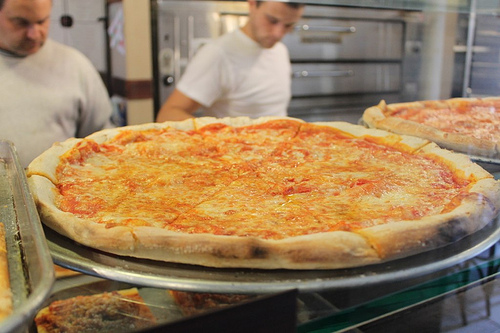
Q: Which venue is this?
A: This is a kitchen.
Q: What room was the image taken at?
A: It was taken at the kitchen.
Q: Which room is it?
A: It is a kitchen.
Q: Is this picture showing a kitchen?
A: Yes, it is showing a kitchen.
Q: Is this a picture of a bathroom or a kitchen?
A: It is showing a kitchen.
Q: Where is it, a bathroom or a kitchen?
A: It is a kitchen.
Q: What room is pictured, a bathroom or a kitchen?
A: It is a kitchen.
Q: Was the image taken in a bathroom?
A: No, the picture was taken in a kitchen.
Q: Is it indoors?
A: Yes, it is indoors.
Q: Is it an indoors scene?
A: Yes, it is indoors.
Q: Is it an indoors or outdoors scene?
A: It is indoors.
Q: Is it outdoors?
A: No, it is indoors.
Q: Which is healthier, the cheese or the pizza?
A: The cheese is healthier than the pizza.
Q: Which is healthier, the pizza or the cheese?
A: The cheese is healthier than the pizza.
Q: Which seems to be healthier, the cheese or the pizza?
A: The cheese is healthier than the pizza.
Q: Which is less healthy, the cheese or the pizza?
A: The pizza is less healthy than the cheese.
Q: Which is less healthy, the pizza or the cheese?
A: The pizza is less healthy than the cheese.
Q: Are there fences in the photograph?
A: No, there are no fences.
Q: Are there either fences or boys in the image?
A: No, there are no fences or boys.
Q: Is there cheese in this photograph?
A: Yes, there is cheese.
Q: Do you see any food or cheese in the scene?
A: Yes, there is cheese.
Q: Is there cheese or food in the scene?
A: Yes, there is cheese.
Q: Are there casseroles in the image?
A: No, there are no casseroles.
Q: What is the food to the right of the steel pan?
A: The food is cheese.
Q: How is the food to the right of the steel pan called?
A: The food is cheese.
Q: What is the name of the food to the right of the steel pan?
A: The food is cheese.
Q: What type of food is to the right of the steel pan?
A: The food is cheese.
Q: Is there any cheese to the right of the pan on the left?
A: Yes, there is cheese to the right of the pan.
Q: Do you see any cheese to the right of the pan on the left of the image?
A: Yes, there is cheese to the right of the pan.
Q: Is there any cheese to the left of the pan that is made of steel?
A: No, the cheese is to the right of the pan.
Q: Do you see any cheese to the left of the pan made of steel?
A: No, the cheese is to the right of the pan.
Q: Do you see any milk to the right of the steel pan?
A: No, there is cheese to the right of the pan.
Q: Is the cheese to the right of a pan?
A: Yes, the cheese is to the right of a pan.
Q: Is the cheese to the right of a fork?
A: No, the cheese is to the right of a pan.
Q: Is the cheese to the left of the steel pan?
A: No, the cheese is to the right of the pan.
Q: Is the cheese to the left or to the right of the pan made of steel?
A: The cheese is to the right of the pan.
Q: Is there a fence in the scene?
A: No, there are no fences.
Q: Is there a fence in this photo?
A: No, there are no fences.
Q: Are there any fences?
A: No, there are no fences.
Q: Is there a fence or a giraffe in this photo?
A: No, there are no fences or giraffes.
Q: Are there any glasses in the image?
A: No, there are no glasses.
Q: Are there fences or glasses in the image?
A: No, there are no glasses or fences.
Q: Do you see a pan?
A: Yes, there is a pan.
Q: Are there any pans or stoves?
A: Yes, there is a pan.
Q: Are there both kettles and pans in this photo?
A: No, there is a pan but no kettles.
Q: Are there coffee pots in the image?
A: No, there are no coffee pots.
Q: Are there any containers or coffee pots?
A: No, there are no coffee pots or containers.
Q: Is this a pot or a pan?
A: This is a pan.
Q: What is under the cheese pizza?
A: The pan is under the pizza.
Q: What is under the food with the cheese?
A: The pan is under the pizza.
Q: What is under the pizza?
A: The pan is under the pizza.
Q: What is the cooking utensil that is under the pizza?
A: The cooking utensil is a pan.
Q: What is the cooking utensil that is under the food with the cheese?
A: The cooking utensil is a pan.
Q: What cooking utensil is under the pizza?
A: The cooking utensil is a pan.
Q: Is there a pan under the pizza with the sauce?
A: Yes, there is a pan under the pizza.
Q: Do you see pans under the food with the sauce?
A: Yes, there is a pan under the pizza.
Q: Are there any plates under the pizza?
A: No, there is a pan under the pizza.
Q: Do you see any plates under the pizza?
A: No, there is a pan under the pizza.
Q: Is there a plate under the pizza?
A: No, there is a pan under the pizza.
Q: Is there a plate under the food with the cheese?
A: No, there is a pan under the pizza.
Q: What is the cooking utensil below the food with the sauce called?
A: The cooking utensil is a pan.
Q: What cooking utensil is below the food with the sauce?
A: The cooking utensil is a pan.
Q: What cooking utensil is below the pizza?
A: The cooking utensil is a pan.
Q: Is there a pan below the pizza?
A: Yes, there is a pan below the pizza.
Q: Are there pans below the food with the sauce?
A: Yes, there is a pan below the pizza.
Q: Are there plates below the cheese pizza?
A: No, there is a pan below the pizza.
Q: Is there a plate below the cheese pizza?
A: No, there is a pan below the pizza.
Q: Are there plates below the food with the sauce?
A: No, there is a pan below the pizza.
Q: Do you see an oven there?
A: Yes, there is an oven.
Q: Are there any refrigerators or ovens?
A: Yes, there is an oven.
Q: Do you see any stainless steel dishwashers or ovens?
A: Yes, there is a stainless steel oven.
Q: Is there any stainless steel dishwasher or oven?
A: Yes, there is a stainless steel oven.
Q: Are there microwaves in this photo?
A: No, there are no microwaves.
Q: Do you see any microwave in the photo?
A: No, there are no microwaves.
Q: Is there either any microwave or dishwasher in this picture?
A: No, there are no microwaves or dishwashers.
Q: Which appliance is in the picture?
A: The appliance is an oven.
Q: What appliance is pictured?
A: The appliance is an oven.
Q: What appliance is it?
A: The appliance is an oven.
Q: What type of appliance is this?
A: This is an oven.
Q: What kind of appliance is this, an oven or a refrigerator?
A: This is an oven.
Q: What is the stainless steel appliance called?
A: The appliance is an oven.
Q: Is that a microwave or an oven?
A: That is an oven.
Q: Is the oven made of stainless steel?
A: Yes, the oven is made of stainless steel.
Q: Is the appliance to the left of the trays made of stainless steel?
A: Yes, the oven is made of stainless steel.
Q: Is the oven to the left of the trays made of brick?
A: No, the oven is made of stainless steel.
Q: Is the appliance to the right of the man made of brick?
A: No, the oven is made of stainless steel.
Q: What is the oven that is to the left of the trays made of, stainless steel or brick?
A: The oven is made of stainless steel.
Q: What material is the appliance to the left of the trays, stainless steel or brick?
A: The oven is made of stainless steel.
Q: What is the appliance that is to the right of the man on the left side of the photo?
A: The appliance is an oven.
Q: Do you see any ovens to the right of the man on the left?
A: Yes, there is an oven to the right of the man.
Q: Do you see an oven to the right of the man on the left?
A: Yes, there is an oven to the right of the man.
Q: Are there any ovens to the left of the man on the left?
A: No, the oven is to the right of the man.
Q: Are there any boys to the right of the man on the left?
A: No, there is an oven to the right of the man.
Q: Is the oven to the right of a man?
A: Yes, the oven is to the right of a man.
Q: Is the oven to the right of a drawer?
A: No, the oven is to the right of a man.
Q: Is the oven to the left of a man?
A: No, the oven is to the right of a man.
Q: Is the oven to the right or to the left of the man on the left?
A: The oven is to the right of the man.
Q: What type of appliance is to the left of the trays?
A: The appliance is an oven.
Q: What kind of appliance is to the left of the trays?
A: The appliance is an oven.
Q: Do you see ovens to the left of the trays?
A: Yes, there is an oven to the left of the trays.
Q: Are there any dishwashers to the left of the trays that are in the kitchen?
A: No, there is an oven to the left of the trays.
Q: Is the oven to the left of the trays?
A: Yes, the oven is to the left of the trays.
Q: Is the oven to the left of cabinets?
A: No, the oven is to the left of the trays.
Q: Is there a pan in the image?
A: Yes, there is a pan.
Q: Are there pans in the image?
A: Yes, there is a pan.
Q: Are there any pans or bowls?
A: Yes, there is a pan.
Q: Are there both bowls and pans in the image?
A: No, there is a pan but no bowls.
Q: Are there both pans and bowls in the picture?
A: No, there is a pan but no bowls.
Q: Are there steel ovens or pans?
A: Yes, there is a steel pan.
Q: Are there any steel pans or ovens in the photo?
A: Yes, there is a steel pan.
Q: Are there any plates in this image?
A: No, there are no plates.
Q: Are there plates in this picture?
A: No, there are no plates.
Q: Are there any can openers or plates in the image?
A: No, there are no plates or can openers.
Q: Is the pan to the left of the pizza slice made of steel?
A: Yes, the pan is made of steel.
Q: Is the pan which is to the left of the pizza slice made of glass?
A: No, the pan is made of steel.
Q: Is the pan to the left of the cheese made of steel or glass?
A: The pan is made of steel.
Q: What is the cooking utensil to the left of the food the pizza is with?
A: The cooking utensil is a pan.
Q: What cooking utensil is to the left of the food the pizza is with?
A: The cooking utensil is a pan.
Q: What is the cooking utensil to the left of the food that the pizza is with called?
A: The cooking utensil is a pan.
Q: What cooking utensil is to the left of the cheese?
A: The cooking utensil is a pan.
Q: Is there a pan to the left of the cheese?
A: Yes, there is a pan to the left of the cheese.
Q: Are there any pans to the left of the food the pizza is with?
A: Yes, there is a pan to the left of the cheese.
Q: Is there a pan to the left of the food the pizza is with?
A: Yes, there is a pan to the left of the cheese.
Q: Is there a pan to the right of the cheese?
A: No, the pan is to the left of the cheese.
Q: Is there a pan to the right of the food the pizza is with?
A: No, the pan is to the left of the cheese.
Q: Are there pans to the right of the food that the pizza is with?
A: No, the pan is to the left of the cheese.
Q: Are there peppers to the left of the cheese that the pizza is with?
A: No, there is a pan to the left of the cheese.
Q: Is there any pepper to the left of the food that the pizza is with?
A: No, there is a pan to the left of the cheese.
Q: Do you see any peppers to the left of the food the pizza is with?
A: No, there is a pan to the left of the cheese.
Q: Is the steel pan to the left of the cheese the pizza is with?
A: Yes, the pan is to the left of the cheese.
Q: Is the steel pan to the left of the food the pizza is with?
A: Yes, the pan is to the left of the cheese.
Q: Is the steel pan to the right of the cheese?
A: No, the pan is to the left of the cheese.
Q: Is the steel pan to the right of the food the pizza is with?
A: No, the pan is to the left of the cheese.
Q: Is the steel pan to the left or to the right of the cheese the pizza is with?
A: The pan is to the left of the cheese.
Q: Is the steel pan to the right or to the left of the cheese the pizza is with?
A: The pan is to the left of the cheese.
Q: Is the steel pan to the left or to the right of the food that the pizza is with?
A: The pan is to the left of the cheese.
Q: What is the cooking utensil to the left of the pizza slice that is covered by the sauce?
A: The cooking utensil is a pan.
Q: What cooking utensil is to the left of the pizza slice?
A: The cooking utensil is a pan.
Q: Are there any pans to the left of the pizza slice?
A: Yes, there is a pan to the left of the pizza slice.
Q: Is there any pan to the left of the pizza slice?
A: Yes, there is a pan to the left of the pizza slice.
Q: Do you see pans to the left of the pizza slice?
A: Yes, there is a pan to the left of the pizza slice.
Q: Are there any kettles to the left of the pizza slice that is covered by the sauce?
A: No, there is a pan to the left of the pizza slice.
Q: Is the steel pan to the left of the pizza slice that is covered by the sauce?
A: Yes, the pan is to the left of the pizza slice.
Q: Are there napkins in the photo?
A: No, there are no napkins.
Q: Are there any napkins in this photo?
A: No, there are no napkins.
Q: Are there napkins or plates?
A: No, there are no napkins or plates.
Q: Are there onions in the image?
A: No, there are no onions.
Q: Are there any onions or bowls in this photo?
A: No, there are no onions or bowls.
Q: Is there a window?
A: Yes, there is a window.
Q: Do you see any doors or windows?
A: Yes, there is a window.